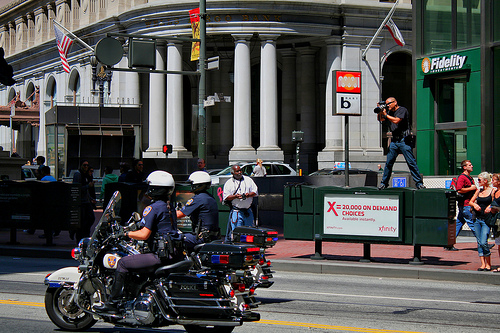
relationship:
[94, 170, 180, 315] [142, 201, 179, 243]
police have shirt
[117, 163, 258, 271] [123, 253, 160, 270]
police have pants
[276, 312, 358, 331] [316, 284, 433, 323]
yellow on road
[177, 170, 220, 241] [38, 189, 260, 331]
officer on a motorcycle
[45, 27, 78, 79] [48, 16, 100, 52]
flag on a pole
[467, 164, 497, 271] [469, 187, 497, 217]
woman in tank top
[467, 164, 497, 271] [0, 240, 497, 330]
woman ready to cross road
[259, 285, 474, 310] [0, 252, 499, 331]
white line on road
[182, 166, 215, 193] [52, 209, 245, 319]
helmet on motorcycle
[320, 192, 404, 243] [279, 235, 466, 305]
xfinity poster on street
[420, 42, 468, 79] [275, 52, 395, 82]
name on building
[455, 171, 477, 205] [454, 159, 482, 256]
shirt on person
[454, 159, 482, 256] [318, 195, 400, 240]
person leaning on sign